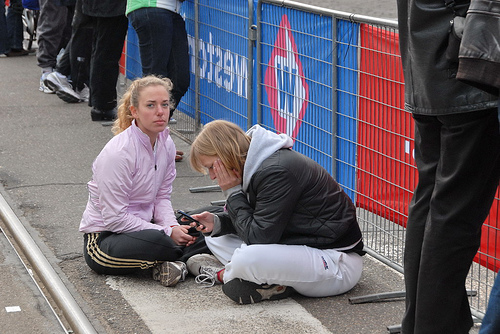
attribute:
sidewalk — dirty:
[1, 65, 499, 332]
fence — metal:
[127, 0, 499, 332]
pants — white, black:
[203, 234, 364, 296]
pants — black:
[83, 229, 221, 275]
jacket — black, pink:
[212, 146, 367, 254]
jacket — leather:
[397, 1, 499, 113]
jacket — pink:
[79, 119, 180, 237]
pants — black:
[89, 17, 129, 114]